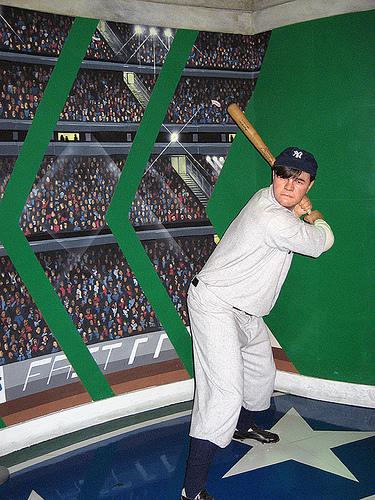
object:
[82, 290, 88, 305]
spectator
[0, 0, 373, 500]
scene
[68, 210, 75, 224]
spectator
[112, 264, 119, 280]
spectator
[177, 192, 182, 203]
spectator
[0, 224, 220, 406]
stands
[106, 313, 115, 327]
spectator